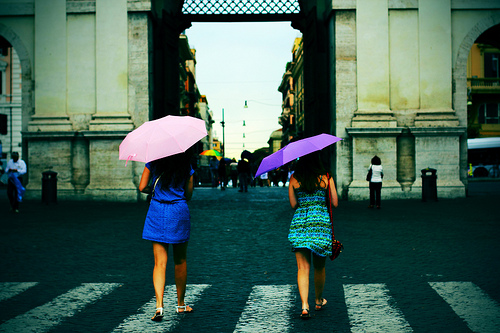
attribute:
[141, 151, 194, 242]
dress — blue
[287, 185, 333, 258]
dress — blue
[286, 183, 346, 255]
dress. — blue, green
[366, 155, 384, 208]
shirt — white 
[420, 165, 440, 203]
trashcans — black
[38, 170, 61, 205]
trashcans — black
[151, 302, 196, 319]
sandals — white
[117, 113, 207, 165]
umbrella — pink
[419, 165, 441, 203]
receptacle — metal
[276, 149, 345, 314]
person — standing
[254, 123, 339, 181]
umbrella — purple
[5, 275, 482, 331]
lines — white 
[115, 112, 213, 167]
umbrella — pink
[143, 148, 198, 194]
hair — black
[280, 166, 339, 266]
dress — green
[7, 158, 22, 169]
shirt — white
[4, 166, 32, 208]
coat — blue